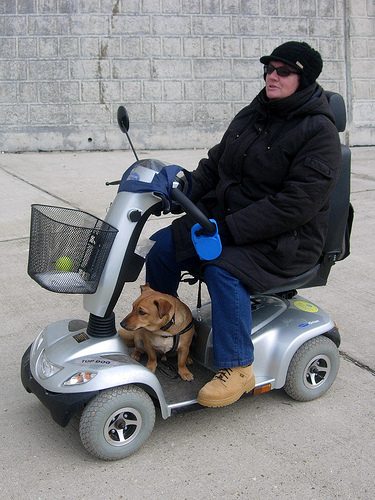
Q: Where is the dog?
A: On scooter.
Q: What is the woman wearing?
A: A coat.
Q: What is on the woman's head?
A: Hat.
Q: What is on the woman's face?
A: Sunglasses.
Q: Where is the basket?
A: On bike.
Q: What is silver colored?
A: Power scooter.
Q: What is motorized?
A: Scooter.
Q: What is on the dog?
A: Harness.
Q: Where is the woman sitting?
A: On scooter.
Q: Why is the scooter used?
A: Travel.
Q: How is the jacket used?
A: Cover.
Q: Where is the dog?
A: On a scooter.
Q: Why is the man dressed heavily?
A: It is cold.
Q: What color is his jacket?
A: Black.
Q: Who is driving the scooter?
A: A man.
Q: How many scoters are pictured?
A: One.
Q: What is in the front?
A: A basket.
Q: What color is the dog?
A: Brown.